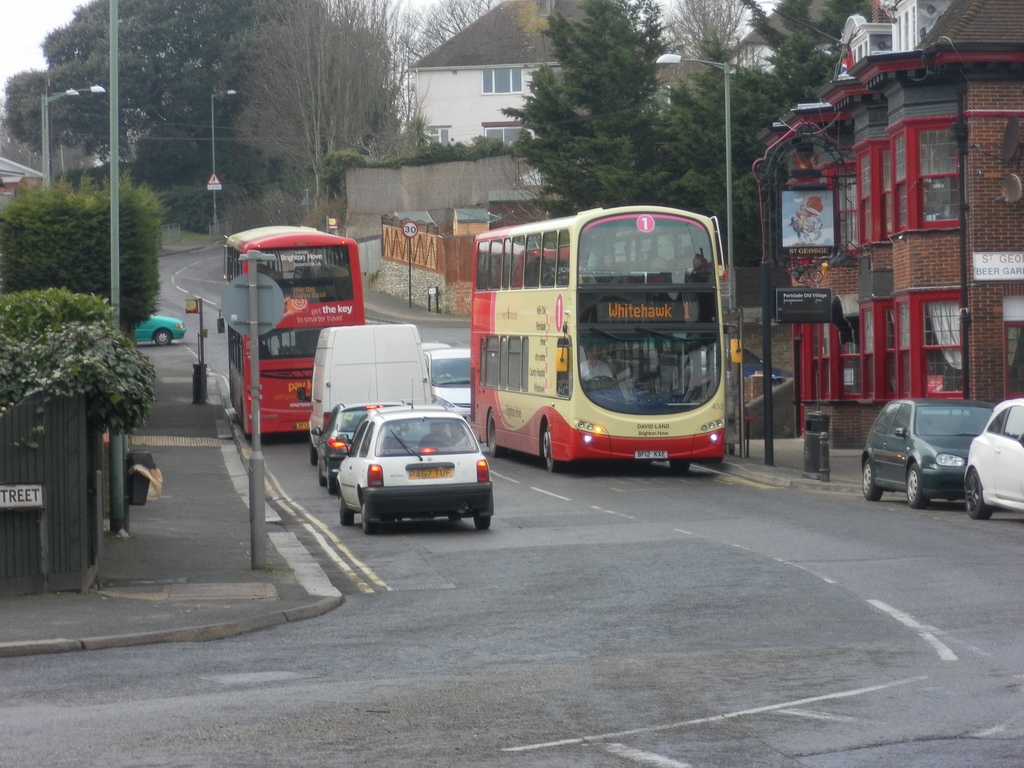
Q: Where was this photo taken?
A: In the city.